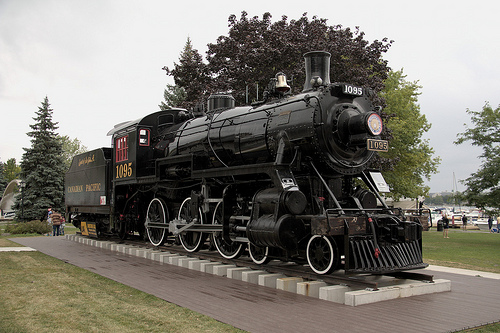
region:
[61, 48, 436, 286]
An old black train engine displayed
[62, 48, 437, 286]
An older train engine display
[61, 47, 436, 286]
An older train engine display in a park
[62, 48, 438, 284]
An older train engine on blocks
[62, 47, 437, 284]
A black train sits in a park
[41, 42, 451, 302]
Single black locomotive on display.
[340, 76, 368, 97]
Number of the train written in white.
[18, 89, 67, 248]
Tall evergreen tree behind the train car.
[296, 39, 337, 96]
Steam chute coming from the top of the train.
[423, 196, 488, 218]
Boats in the harbor.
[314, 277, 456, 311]
Large cement bricks the train is standing on .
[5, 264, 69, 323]
Ground covered in grass.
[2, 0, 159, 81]
Grey cloudy sky.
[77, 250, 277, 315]
Puddles of water collected on the ground from the rain.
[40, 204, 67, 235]
Group of people standing behind the train.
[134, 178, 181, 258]
wheel of a train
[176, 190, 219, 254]
wheel of a train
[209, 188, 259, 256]
wheel of a train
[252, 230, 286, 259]
wheel of a train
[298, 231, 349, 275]
wheel of a train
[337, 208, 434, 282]
bumper of a train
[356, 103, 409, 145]
light of a train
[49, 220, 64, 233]
leg of a person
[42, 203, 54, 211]
head of a person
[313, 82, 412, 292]
the front of a train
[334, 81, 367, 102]
a number of a train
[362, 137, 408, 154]
the license plate of a train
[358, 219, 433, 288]
the front grill of a train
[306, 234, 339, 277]
the front wheel of a train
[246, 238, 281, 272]
the small wheel of a train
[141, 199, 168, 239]
the big wheel of a train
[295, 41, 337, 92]
the exhaust pipe of a train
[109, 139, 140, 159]
the side window of a train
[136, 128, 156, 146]
the front window of a train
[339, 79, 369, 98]
NUMBER FOR DISPLAY TRAIN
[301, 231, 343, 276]
WHEEL FOR TRAIN ON DISPLAY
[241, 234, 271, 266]
WHEEL FOR TRAIN ON DISPLAY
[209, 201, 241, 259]
WHEEL FOR TRAIN ON DISPLAY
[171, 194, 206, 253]
WHEEL FOR TRAIN ON DISPLAY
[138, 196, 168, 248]
WHEEL FOR TRAIN ON DISPLAY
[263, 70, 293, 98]
BELL FOR TRAIN ON DISPLAY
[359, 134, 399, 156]
LICENSE TAG FOR DISPLAY TRAIN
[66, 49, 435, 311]
BLACK TRAIN ON DISPLAY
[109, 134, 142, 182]
SIDE SIGN FOR DISPLAY TRAIN